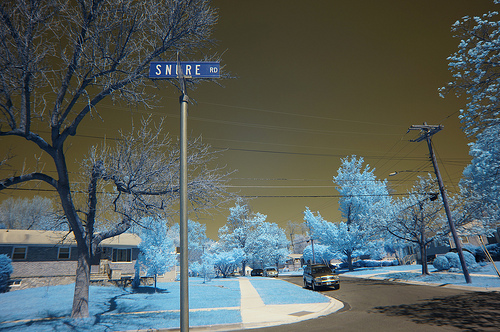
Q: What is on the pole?
A: A street sign.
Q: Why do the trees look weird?
A: Snow.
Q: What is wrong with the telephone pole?
A: Leaning.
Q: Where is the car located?
A: Street.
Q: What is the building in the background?
A: House.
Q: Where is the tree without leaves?
A: Behind sign.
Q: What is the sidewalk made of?
A: Concrete.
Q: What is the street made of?
A: Pavement.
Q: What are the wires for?
A: Electricity.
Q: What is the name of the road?
A: The name of the road is Snare Road.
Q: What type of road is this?
A: A asphalt road.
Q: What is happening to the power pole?
A: It is leaning.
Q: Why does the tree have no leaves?
A: Too early in the season.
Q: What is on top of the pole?
A: A street sign.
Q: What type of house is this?
A: A ranch style house.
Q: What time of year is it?
A: Winter time.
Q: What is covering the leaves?
A: Snow.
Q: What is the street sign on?
A: A pole.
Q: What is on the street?
A: A vehicle.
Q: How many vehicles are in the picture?
A: Three.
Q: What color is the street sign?
A: Blue.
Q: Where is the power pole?
A: Next to the street.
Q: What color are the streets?
A: Grey.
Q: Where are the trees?
A: In the grass.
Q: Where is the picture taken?
A: At a suburban intersection.